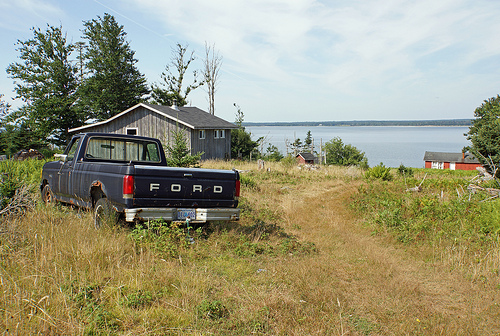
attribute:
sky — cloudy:
[267, 35, 459, 109]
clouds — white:
[227, 22, 480, 109]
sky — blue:
[4, 0, 498, 119]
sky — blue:
[268, 17, 468, 91]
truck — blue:
[34, 130, 246, 234]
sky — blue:
[271, 20, 368, 103]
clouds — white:
[225, 28, 343, 105]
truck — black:
[37, 115, 255, 247]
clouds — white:
[153, 1, 498, 81]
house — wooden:
[60, 93, 254, 155]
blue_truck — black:
[32, 124, 247, 252]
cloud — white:
[154, 2, 316, 56]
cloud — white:
[324, 5, 464, 85]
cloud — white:
[162, 5, 322, 55]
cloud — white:
[332, 8, 449, 101]